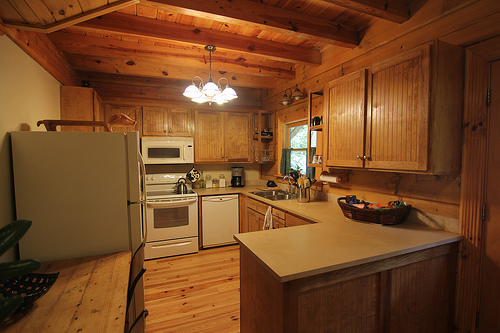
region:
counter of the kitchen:
[303, 241, 378, 270]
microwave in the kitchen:
[135, 137, 205, 169]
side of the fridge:
[29, 163, 144, 243]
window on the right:
[290, 123, 322, 179]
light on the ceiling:
[160, 72, 247, 109]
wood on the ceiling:
[95, 13, 187, 73]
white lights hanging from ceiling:
[160, 74, 247, 116]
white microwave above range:
[129, 134, 211, 176]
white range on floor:
[144, 194, 197, 256]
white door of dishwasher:
[199, 195, 245, 245]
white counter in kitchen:
[270, 189, 440, 279]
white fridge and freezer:
[10, 121, 138, 256]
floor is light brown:
[180, 249, 237, 331]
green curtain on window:
[290, 143, 322, 180]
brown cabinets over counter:
[301, 43, 472, 177]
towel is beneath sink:
[256, 198, 291, 244]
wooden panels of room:
[376, 169, 456, 224]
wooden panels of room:
[382, 22, 463, 52]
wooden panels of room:
[195, 288, 230, 324]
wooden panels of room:
[98, 255, 127, 331]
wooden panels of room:
[147, 255, 207, 277]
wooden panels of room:
[76, 34, 306, 90]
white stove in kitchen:
[135, 171, 204, 261]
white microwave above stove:
[133, 135, 200, 165]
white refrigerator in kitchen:
[10, 120, 152, 272]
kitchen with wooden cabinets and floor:
[0, 0, 495, 328]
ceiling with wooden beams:
[5, 0, 490, 97]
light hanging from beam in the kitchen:
[180, 37, 236, 107]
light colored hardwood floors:
[135, 242, 257, 328]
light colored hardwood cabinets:
[53, 85, 461, 200]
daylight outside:
[285, 115, 316, 173]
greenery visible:
[288, 125, 311, 171]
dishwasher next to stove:
[196, 193, 241, 244]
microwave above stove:
[140, 136, 200, 252]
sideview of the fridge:
[9, 126, 150, 328]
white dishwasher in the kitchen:
[201, 194, 238, 248]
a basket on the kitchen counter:
[337, 195, 412, 225]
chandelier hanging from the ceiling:
[180, 44, 237, 105]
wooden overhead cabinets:
[320, 38, 462, 177]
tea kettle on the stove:
[177, 177, 188, 194]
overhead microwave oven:
[142, 135, 194, 165]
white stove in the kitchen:
[140, 172, 196, 259]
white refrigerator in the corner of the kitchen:
[10, 130, 145, 332]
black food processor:
[230, 166, 241, 186]